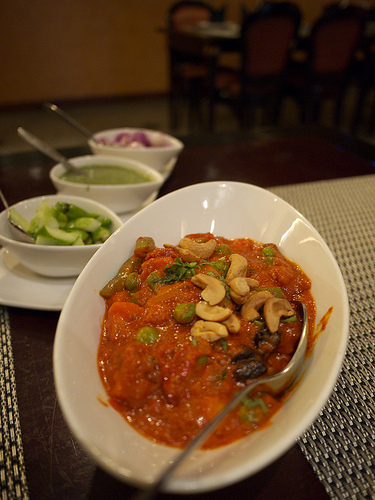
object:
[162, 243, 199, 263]
nuts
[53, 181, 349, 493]
bowl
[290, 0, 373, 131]
chairs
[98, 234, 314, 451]
soup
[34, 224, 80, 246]
apples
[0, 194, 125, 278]
bowl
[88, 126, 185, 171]
bowl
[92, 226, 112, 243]
chunks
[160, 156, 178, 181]
dish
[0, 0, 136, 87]
wall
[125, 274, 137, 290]
peas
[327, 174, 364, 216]
mat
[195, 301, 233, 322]
cashews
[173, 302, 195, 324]
pea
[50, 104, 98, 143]
spoon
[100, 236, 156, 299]
vegetables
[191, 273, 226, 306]
cashew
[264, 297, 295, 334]
cashew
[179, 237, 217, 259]
cashew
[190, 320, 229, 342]
cashew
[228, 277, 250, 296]
cashew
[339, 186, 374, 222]
table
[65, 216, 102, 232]
apples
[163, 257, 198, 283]
pants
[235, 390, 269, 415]
food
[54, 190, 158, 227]
dish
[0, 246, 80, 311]
dish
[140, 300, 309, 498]
spoon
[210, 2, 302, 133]
chairs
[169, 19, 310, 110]
table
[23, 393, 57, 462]
counter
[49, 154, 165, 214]
bowl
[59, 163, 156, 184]
guacamole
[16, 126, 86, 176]
spoon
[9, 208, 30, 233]
veggies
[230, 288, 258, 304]
nuts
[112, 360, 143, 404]
red sauce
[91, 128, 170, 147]
something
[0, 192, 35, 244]
spoon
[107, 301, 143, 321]
stuff